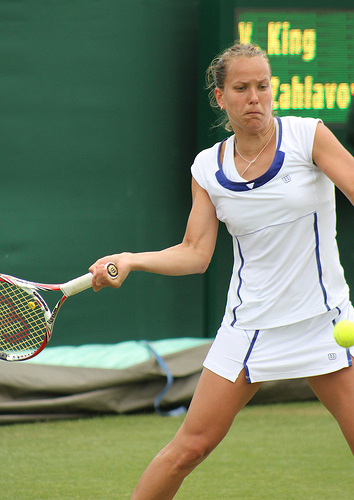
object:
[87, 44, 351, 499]
player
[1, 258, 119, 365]
racket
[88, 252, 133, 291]
hand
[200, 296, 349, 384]
skirt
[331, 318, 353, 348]
ball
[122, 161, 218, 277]
arm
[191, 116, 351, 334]
top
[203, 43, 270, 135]
hair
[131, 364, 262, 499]
leg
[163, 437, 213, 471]
knee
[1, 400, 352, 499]
grass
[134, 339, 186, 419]
strap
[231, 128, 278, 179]
necklace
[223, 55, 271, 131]
face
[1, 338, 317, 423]
tarp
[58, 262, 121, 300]
handle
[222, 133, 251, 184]
tank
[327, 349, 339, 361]
logo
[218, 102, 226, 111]
earring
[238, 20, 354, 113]
words